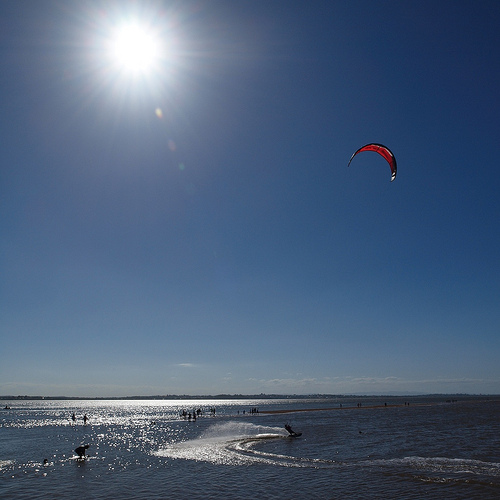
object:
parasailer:
[347, 142, 397, 181]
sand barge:
[205, 400, 458, 419]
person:
[75, 443, 91, 459]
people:
[71, 411, 89, 426]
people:
[181, 408, 216, 423]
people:
[404, 401, 410, 407]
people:
[357, 401, 362, 408]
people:
[249, 407, 261, 415]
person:
[72, 437, 89, 471]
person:
[284, 419, 302, 437]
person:
[66, 412, 78, 421]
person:
[81, 412, 88, 423]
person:
[181, 409, 189, 417]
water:
[0, 397, 499, 499]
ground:
[438, 134, 460, 167]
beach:
[0, 391, 500, 498]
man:
[284, 420, 297, 438]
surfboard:
[283, 432, 302, 439]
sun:
[93, 4, 178, 88]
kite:
[348, 142, 398, 181]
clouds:
[165, 358, 485, 386]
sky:
[0, 0, 497, 392]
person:
[69, 444, 89, 460]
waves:
[160, 462, 211, 496]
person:
[280, 417, 312, 445]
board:
[288, 433, 303, 438]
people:
[284, 423, 303, 439]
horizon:
[2, 393, 500, 398]